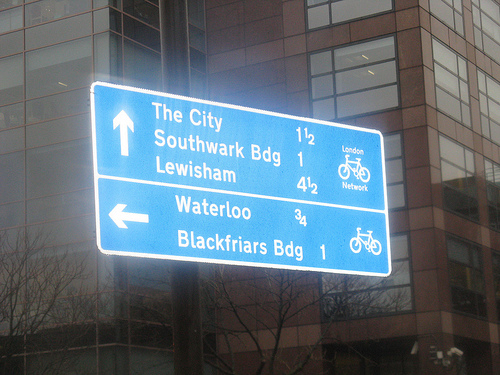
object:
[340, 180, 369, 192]
sign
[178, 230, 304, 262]
blackfriears bdg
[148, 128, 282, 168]
word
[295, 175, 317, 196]
sign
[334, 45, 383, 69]
window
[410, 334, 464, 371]
cameras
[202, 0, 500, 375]
building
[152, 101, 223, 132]
city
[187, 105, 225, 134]
word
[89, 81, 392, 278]
street sign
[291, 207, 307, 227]
sign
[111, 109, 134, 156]
arrow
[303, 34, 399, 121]
windows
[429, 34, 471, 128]
windows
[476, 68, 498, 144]
windows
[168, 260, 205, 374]
pole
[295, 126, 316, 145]
sign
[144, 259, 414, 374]
tree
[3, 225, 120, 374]
tree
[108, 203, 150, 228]
arrow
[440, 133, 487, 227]
windows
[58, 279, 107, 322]
reflection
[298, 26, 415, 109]
windows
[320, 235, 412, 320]
window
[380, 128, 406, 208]
window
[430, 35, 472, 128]
window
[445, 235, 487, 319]
window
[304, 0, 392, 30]
frame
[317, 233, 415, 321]
frame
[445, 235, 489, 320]
frame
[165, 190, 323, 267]
writing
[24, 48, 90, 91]
glass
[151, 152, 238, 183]
word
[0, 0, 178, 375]
building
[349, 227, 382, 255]
symbol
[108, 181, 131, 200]
light